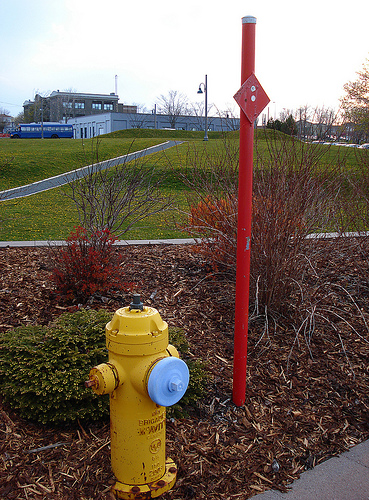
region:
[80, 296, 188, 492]
A blue and yellow fire hydrant.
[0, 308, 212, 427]
A small bush is behind the hydrant.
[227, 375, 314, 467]
Mulch.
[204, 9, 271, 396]
A red metal pole.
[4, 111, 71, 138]
A blue bus.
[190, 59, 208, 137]
A streetlight.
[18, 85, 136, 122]
A large multistory building.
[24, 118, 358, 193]
A small hill.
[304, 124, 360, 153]
A parking lot in the distance.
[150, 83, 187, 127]
The tree has no leaves.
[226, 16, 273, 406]
Red pole with diamond shape at top.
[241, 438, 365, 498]
Sidewalk by hydrant.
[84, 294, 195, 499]
Yellow fire hydrant.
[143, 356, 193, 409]
Blue area on fire hydrant.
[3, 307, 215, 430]
Green bush next to hydrant.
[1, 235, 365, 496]
Wood mulch on the ground.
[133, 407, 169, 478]
Name of company on the hydrant.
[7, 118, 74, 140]
Blue bus in the background.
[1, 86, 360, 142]
Buildings in the background.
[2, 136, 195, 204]
Road up to the buildings.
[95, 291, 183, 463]
yelow fire hydrant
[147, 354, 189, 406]
gray cap on yellow hydrant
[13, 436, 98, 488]
brown bark mulch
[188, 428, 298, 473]
brown bark mulch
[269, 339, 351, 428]
brown bark mulch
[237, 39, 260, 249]
red and gray metal pole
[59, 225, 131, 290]
red bush in brown bark mulch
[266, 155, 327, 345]
red bush in brown bark mulch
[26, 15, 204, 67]
white clouds against blue sky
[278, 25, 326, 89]
white clouds against blue sky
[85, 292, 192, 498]
Short yellow fire hydrant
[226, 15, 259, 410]
Long red metal pole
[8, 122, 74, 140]
Long blue bus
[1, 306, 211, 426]
Short green bush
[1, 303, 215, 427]
Short green bush next to long red pole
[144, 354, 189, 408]
Blue circle on fire hydrant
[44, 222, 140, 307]
Bush with red leaves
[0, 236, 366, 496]
Brown mulch around fire hydrant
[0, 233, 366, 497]
Brown mulch around red pole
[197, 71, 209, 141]
Tall light pole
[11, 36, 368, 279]
picture of a school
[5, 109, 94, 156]
a blue school bus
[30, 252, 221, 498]
a yellow fire hydrant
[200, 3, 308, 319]
a red pole in the foreground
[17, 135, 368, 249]
lots of green space to run around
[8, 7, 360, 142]
a cloudy sky overhead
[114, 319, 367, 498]
barely noticeable sidewalk in the picture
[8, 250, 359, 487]
mulch under the bushes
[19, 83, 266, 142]
two separate sections of a school building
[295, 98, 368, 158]
park cars and residential housing